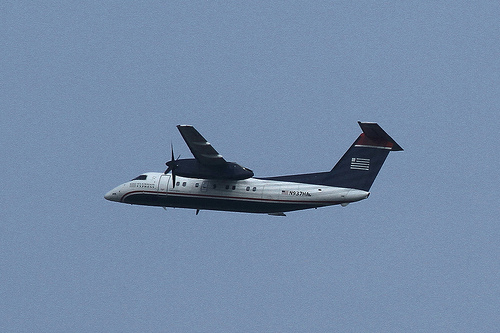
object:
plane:
[103, 121, 403, 216]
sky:
[1, 2, 500, 332]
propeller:
[165, 144, 180, 190]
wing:
[161, 125, 258, 184]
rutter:
[358, 122, 403, 151]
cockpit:
[103, 173, 148, 207]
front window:
[134, 175, 148, 181]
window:
[181, 183, 187, 186]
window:
[176, 180, 180, 187]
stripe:
[121, 190, 345, 204]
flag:
[350, 157, 371, 172]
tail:
[332, 122, 404, 189]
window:
[224, 183, 230, 190]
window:
[230, 185, 235, 191]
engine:
[173, 158, 255, 180]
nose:
[104, 187, 117, 204]